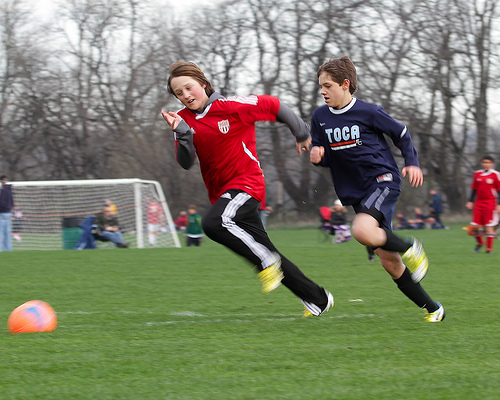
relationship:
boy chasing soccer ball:
[159, 60, 335, 319] [8, 298, 56, 336]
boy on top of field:
[159, 60, 335, 319] [0, 221, 498, 394]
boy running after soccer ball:
[308, 56, 446, 323] [8, 298, 56, 336]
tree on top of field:
[244, 1, 364, 220] [0, 221, 498, 394]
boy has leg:
[159, 60, 335, 319] [202, 189, 275, 266]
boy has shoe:
[159, 60, 335, 319] [260, 250, 284, 293]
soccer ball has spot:
[8, 298, 56, 336] [26, 307, 40, 318]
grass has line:
[0, 227, 499, 396] [0, 308, 374, 328]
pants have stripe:
[202, 190, 327, 316] [222, 192, 276, 269]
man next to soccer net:
[0, 176, 17, 251] [1, 176, 182, 248]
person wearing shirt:
[187, 202, 204, 246] [186, 214, 203, 236]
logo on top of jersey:
[323, 124, 362, 151] [311, 96, 419, 205]